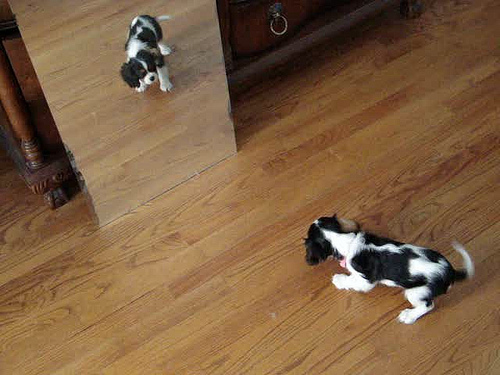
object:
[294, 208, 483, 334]
puppy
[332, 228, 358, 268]
collar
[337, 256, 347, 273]
orange tag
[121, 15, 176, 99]
reflection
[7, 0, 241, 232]
mirror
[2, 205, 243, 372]
floor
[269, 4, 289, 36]
handle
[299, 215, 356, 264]
floppy ears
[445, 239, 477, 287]
tail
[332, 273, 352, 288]
paw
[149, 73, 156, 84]
nose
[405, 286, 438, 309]
thigh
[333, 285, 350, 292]
edge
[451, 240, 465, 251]
tip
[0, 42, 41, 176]
post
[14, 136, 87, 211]
decorations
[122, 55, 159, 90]
face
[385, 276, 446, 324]
paws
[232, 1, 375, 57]
dresser drawer